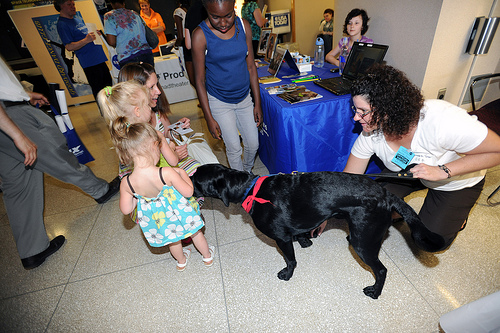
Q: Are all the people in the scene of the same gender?
A: No, they are both male and female.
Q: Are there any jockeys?
A: No, there are no jockeys.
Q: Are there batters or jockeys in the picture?
A: No, there are no jockeys or batters.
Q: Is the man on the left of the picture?
A: Yes, the man is on the left of the image.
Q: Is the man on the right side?
A: No, the man is on the left of the image.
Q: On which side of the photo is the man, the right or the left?
A: The man is on the left of the image.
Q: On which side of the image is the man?
A: The man is on the left of the image.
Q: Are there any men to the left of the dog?
A: Yes, there is a man to the left of the dog.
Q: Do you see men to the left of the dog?
A: Yes, there is a man to the left of the dog.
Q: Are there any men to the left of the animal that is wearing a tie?
A: Yes, there is a man to the left of the dog.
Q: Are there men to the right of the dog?
A: No, the man is to the left of the dog.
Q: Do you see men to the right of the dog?
A: No, the man is to the left of the dog.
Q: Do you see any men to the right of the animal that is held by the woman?
A: No, the man is to the left of the dog.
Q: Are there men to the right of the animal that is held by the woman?
A: No, the man is to the left of the dog.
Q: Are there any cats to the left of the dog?
A: No, there is a man to the left of the dog.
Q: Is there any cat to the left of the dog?
A: No, there is a man to the left of the dog.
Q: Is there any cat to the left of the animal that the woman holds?
A: No, there is a man to the left of the dog.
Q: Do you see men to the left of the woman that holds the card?
A: Yes, there is a man to the left of the woman.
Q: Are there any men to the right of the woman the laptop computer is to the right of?
A: No, the man is to the left of the woman.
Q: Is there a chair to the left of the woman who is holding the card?
A: No, there is a man to the left of the woman.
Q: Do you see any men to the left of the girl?
A: Yes, there is a man to the left of the girl.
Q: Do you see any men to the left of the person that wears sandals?
A: Yes, there is a man to the left of the girl.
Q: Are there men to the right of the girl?
A: No, the man is to the left of the girl.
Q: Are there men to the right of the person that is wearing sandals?
A: No, the man is to the left of the girl.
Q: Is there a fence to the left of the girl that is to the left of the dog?
A: No, there is a man to the left of the girl.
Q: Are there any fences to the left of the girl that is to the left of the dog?
A: No, there is a man to the left of the girl.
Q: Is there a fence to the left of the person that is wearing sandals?
A: No, there is a man to the left of the girl.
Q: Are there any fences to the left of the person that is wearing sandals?
A: No, there is a man to the left of the girl.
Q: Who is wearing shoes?
A: The man is wearing shoes.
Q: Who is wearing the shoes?
A: The man is wearing shoes.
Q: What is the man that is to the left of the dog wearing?
A: The man is wearing shoes.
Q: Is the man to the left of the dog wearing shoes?
A: Yes, the man is wearing shoes.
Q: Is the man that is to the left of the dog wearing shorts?
A: No, the man is wearing shoes.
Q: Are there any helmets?
A: No, there are no helmets.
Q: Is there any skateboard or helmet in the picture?
A: No, there are no helmets or skateboards.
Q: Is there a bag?
A: No, there are no bags.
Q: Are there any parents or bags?
A: No, there are no bags or parents.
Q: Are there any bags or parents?
A: No, there are no bags or parents.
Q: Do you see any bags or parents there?
A: No, there are no bags or parents.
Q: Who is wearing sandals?
A: The girl is wearing sandals.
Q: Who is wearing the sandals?
A: The girl is wearing sandals.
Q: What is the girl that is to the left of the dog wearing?
A: The girl is wearing sandals.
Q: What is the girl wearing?
A: The girl is wearing sandals.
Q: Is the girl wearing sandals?
A: Yes, the girl is wearing sandals.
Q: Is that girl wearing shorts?
A: No, the girl is wearing sandals.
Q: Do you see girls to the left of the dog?
A: Yes, there is a girl to the left of the dog.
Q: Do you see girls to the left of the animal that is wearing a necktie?
A: Yes, there is a girl to the left of the dog.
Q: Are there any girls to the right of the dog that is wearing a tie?
A: No, the girl is to the left of the dog.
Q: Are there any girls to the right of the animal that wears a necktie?
A: No, the girl is to the left of the dog.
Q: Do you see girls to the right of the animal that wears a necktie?
A: No, the girl is to the left of the dog.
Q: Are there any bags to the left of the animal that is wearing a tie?
A: No, there is a girl to the left of the dog.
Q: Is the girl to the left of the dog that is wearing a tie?
A: Yes, the girl is to the left of the dog.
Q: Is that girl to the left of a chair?
A: No, the girl is to the left of the dog.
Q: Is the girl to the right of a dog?
A: No, the girl is to the left of a dog.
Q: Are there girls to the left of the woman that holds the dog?
A: Yes, there is a girl to the left of the woman.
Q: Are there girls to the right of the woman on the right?
A: No, the girl is to the left of the woman.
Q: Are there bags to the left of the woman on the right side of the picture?
A: No, there is a girl to the left of the woman.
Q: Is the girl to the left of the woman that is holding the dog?
A: Yes, the girl is to the left of the woman.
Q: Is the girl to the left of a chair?
A: No, the girl is to the left of the woman.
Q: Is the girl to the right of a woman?
A: No, the girl is to the left of a woman.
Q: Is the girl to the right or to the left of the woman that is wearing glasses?
A: The girl is to the left of the woman.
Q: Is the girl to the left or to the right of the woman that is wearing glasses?
A: The girl is to the left of the woman.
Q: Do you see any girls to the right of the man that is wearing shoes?
A: Yes, there is a girl to the right of the man.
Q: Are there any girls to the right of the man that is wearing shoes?
A: Yes, there is a girl to the right of the man.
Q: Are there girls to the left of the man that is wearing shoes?
A: No, the girl is to the right of the man.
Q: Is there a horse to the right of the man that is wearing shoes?
A: No, there is a girl to the right of the man.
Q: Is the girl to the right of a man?
A: Yes, the girl is to the right of a man.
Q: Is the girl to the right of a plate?
A: No, the girl is to the right of a man.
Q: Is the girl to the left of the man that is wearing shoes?
A: No, the girl is to the right of the man.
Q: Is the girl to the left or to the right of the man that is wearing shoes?
A: The girl is to the right of the man.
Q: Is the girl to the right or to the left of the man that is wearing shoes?
A: The girl is to the right of the man.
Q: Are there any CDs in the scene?
A: No, there are no cds.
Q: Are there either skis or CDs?
A: No, there are no CDs or skis.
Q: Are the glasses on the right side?
A: Yes, the glasses are on the right of the image.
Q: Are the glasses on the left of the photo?
A: No, the glasses are on the right of the image.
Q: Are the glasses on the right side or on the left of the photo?
A: The glasses are on the right of the image.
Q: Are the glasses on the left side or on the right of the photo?
A: The glasses are on the right of the image.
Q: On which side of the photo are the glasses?
A: The glasses are on the right of the image.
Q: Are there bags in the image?
A: No, there are no bags.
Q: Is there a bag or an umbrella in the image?
A: No, there are no bags or umbrellas.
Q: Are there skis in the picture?
A: No, there are no skis.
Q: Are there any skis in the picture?
A: No, there are no skis.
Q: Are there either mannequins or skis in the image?
A: No, there are no skis or mannequins.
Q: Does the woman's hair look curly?
A: Yes, the hair is curly.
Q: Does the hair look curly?
A: Yes, the hair is curly.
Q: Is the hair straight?
A: No, the hair is curly.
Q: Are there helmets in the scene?
A: No, there are no helmets.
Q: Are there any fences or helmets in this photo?
A: No, there are no helmets or fences.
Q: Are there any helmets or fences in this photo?
A: No, there are no helmets or fences.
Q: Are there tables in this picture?
A: Yes, there is a table.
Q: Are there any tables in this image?
A: Yes, there is a table.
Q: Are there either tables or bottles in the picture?
A: Yes, there is a table.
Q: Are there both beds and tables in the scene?
A: No, there is a table but no beds.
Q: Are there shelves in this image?
A: No, there are no shelves.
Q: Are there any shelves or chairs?
A: No, there are no shelves or chairs.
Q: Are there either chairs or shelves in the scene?
A: No, there are no shelves or chairs.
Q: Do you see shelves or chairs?
A: No, there are no shelves or chairs.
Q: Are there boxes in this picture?
A: No, there are no boxes.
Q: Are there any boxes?
A: No, there are no boxes.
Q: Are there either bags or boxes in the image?
A: No, there are no boxes or bags.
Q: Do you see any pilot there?
A: No, there are no pilots.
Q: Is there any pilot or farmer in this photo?
A: No, there are no pilots or farmers.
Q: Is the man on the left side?
A: Yes, the man is on the left of the image.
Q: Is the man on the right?
A: No, the man is on the left of the image.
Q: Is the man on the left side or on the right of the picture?
A: The man is on the left of the image.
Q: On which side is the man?
A: The man is on the left of the image.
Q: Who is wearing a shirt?
A: The man is wearing a shirt.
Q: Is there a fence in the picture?
A: No, there are no fences.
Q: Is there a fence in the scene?
A: No, there are no fences.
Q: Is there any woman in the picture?
A: Yes, there is a woman.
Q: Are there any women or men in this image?
A: Yes, there is a woman.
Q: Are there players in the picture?
A: No, there are no players.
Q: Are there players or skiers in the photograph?
A: No, there are no players or skiers.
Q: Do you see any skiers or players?
A: No, there are no players or skiers.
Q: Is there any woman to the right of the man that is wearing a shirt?
A: Yes, there is a woman to the right of the man.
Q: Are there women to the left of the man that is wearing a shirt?
A: No, the woman is to the right of the man.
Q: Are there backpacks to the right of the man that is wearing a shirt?
A: No, there is a woman to the right of the man.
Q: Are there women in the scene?
A: Yes, there is a woman.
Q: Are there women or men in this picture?
A: Yes, there is a woman.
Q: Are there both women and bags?
A: No, there is a woman but no bags.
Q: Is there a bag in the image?
A: No, there are no bags.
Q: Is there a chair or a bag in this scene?
A: No, there are no bags or chairs.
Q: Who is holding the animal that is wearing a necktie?
A: The woman is holding the dog.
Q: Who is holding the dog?
A: The woman is holding the dog.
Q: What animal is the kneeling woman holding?
A: The woman is holding the dog.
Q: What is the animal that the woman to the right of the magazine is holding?
A: The animal is a dog.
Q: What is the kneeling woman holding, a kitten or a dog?
A: The woman is holding a dog.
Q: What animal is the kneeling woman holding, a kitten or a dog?
A: The woman is holding a dog.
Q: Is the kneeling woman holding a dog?
A: Yes, the woman is holding a dog.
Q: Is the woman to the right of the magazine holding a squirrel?
A: No, the woman is holding a dog.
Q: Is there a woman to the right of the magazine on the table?
A: Yes, there is a woman to the right of the magazine.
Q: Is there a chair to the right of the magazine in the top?
A: No, there is a woman to the right of the magazine.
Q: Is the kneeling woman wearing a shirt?
A: Yes, the woman is wearing a shirt.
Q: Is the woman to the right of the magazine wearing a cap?
A: No, the woman is wearing a shirt.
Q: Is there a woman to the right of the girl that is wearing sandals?
A: Yes, there is a woman to the right of the girl.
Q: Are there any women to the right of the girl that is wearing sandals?
A: Yes, there is a woman to the right of the girl.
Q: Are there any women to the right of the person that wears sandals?
A: Yes, there is a woman to the right of the girl.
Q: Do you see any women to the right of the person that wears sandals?
A: Yes, there is a woman to the right of the girl.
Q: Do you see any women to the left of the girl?
A: No, the woman is to the right of the girl.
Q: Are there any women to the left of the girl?
A: No, the woman is to the right of the girl.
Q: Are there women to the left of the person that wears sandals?
A: No, the woman is to the right of the girl.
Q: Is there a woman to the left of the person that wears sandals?
A: No, the woman is to the right of the girl.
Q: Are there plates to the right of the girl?
A: No, there is a woman to the right of the girl.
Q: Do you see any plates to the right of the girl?
A: No, there is a woman to the right of the girl.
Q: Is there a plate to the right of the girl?
A: No, there is a woman to the right of the girl.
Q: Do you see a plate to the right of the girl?
A: No, there is a woman to the right of the girl.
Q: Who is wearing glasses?
A: The woman is wearing glasses.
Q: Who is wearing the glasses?
A: The woman is wearing glasses.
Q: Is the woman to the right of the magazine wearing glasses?
A: Yes, the woman is wearing glasses.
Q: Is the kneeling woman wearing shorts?
A: No, the woman is wearing glasses.